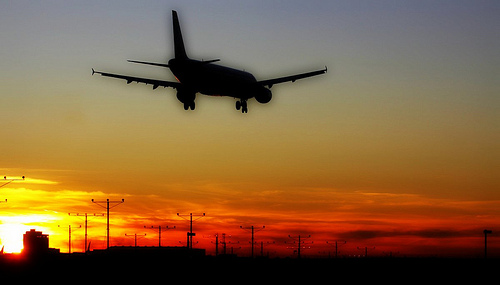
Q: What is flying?
A: Plane.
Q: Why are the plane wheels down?
A: To land.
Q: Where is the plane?
A: In sky.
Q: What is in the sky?
A: Airplane.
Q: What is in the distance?
A: The sun.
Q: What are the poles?
A: Electric poles.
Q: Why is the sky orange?
A: The sun.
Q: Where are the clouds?
A: There are none.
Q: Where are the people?
A: On the plane.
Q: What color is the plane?
A: Black.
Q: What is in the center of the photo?
A: Airplane.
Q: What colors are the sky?
A: Blue, yellow, and red.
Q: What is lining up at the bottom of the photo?
A: Telephone poles.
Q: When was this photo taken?
A: Evening.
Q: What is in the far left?
A: Bright reflection from the sun.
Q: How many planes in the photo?
A: One.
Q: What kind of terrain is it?
A: Flat.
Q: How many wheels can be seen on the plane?
A: Four.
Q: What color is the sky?
A: Orange.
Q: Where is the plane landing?
A: Airport.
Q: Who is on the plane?
A: Passengers.